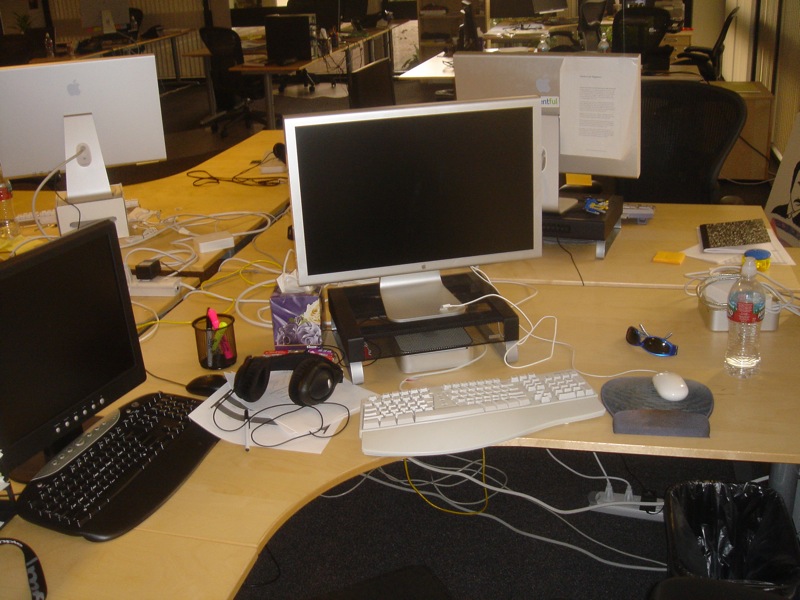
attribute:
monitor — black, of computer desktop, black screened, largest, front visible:
[0, 220, 147, 477]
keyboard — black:
[18, 394, 226, 547]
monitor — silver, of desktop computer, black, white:
[278, 98, 548, 288]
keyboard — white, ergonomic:
[357, 367, 608, 458]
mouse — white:
[651, 367, 688, 403]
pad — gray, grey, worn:
[599, 372, 717, 443]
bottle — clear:
[726, 260, 767, 370]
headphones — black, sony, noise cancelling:
[233, 350, 345, 406]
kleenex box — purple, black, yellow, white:
[270, 282, 323, 351]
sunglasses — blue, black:
[623, 323, 679, 357]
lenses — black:
[647, 337, 668, 352]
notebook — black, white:
[698, 219, 772, 257]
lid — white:
[741, 260, 755, 279]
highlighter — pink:
[206, 308, 236, 361]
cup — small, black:
[193, 315, 241, 370]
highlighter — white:
[204, 320, 214, 367]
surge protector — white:
[127, 262, 187, 299]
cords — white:
[127, 244, 204, 282]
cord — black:
[135, 257, 163, 278]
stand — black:
[327, 273, 521, 361]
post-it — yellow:
[562, 172, 598, 187]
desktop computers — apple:
[1, 56, 651, 351]